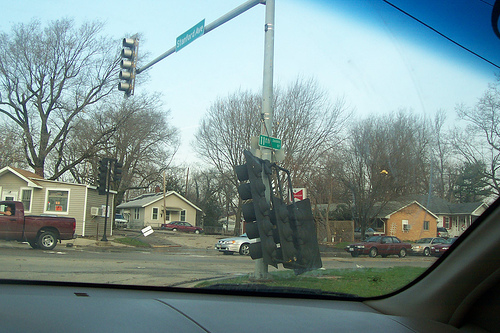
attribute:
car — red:
[345, 232, 415, 257]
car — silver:
[215, 228, 262, 260]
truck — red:
[3, 193, 81, 251]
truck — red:
[1, 196, 77, 254]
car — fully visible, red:
[345, 229, 414, 260]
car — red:
[163, 216, 205, 234]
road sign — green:
[255, 131, 284, 155]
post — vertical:
[260, 3, 285, 171]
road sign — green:
[174, 17, 205, 53]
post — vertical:
[134, 1, 275, 76]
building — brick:
[313, 197, 436, 242]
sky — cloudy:
[9, 6, 498, 123]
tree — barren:
[4, 17, 124, 186]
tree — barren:
[63, 105, 175, 196]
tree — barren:
[193, 79, 346, 225]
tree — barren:
[347, 111, 439, 206]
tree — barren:
[3, 18, 137, 183]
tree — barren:
[195, 82, 333, 233]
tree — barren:
[341, 115, 429, 224]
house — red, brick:
[312, 199, 446, 244]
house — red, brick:
[310, 196, 440, 246]